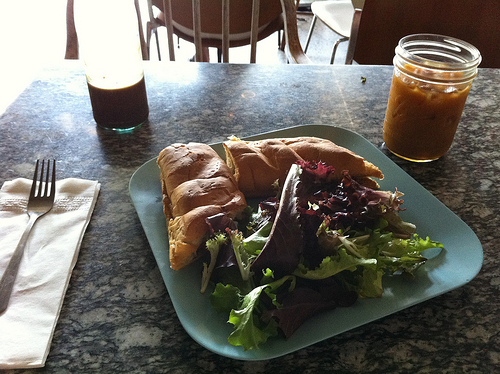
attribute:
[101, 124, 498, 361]
plate — green, light blue, square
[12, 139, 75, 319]
fork — metal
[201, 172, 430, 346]
salad — undressed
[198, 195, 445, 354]
salad. — green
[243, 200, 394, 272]
salad — purple, a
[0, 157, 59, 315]
fork — unused, silver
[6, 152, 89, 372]
napkin — white, unused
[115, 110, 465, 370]
plate — square, white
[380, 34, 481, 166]
jar — small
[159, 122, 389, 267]
bread — light brown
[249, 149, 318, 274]
lettuce — green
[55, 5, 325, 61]
chair — wooden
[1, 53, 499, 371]
table — grey, granite, light grey